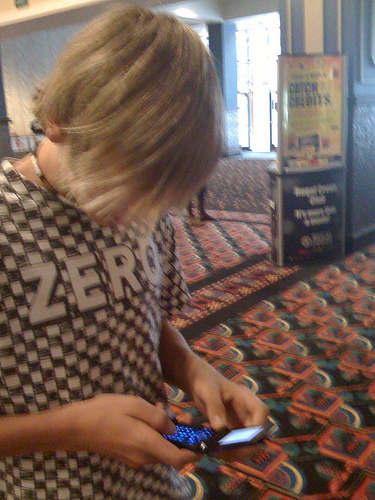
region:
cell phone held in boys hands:
[156, 412, 272, 457]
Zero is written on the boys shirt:
[18, 232, 195, 329]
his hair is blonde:
[24, 2, 225, 233]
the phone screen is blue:
[220, 426, 267, 440]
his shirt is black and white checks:
[2, 162, 212, 499]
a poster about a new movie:
[276, 51, 347, 172]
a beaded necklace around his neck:
[25, 148, 64, 203]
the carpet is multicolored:
[175, 257, 371, 496]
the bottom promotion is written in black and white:
[274, 170, 353, 262]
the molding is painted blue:
[324, 1, 336, 51]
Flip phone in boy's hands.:
[159, 410, 287, 455]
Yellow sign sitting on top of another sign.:
[273, 50, 343, 165]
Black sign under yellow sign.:
[261, 158, 352, 269]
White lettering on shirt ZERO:
[12, 231, 172, 332]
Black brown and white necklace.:
[21, 148, 85, 210]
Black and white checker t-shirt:
[1, 153, 199, 498]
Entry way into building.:
[1, 9, 280, 211]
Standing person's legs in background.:
[183, 187, 220, 225]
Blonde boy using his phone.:
[1, 5, 273, 498]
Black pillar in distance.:
[203, 13, 237, 168]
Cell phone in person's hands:
[142, 406, 272, 457]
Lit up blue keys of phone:
[160, 421, 214, 447]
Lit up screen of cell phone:
[218, 424, 265, 449]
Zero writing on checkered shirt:
[13, 237, 172, 327]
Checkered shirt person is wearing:
[0, 152, 196, 499]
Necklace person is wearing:
[22, 139, 62, 197]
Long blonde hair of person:
[25, 5, 236, 235]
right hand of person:
[76, 385, 205, 477]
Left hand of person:
[187, 362, 277, 441]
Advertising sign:
[267, 50, 355, 270]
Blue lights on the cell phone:
[180, 427, 196, 442]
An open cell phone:
[169, 415, 271, 445]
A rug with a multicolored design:
[290, 328, 355, 471]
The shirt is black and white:
[20, 341, 151, 370]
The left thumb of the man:
[204, 398, 223, 428]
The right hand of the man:
[87, 397, 179, 466]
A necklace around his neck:
[24, 153, 47, 183]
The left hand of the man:
[193, 372, 264, 426]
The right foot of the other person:
[196, 208, 213, 220]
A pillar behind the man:
[209, 23, 240, 158]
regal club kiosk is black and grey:
[267, 50, 350, 269]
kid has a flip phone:
[162, 416, 278, 455]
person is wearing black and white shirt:
[0, 154, 192, 499]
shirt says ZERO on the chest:
[12, 234, 164, 325]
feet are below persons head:
[187, 175, 219, 227]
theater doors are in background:
[237, 23, 279, 151]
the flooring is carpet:
[0, 151, 374, 499]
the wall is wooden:
[1, 17, 95, 132]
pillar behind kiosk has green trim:
[280, 0, 372, 252]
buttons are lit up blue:
[156, 421, 213, 449]